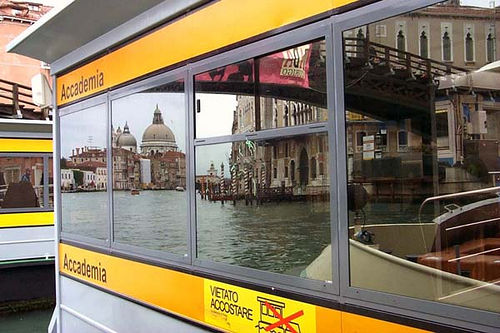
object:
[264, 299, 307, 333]
x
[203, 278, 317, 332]
sign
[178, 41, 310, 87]
banner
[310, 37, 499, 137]
bridge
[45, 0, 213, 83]
stripe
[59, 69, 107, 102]
writing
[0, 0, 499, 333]
background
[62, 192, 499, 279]
water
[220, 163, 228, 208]
pole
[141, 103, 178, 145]
dome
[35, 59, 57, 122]
person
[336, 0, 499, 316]
window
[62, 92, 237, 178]
sky